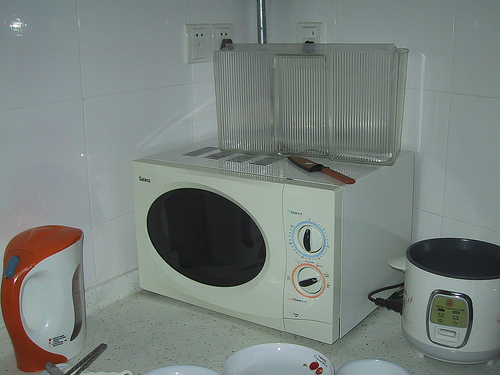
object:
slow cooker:
[402, 237, 499, 366]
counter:
[0, 291, 498, 373]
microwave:
[129, 134, 415, 345]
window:
[145, 184, 268, 287]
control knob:
[297, 224, 323, 252]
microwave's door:
[129, 157, 343, 345]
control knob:
[299, 267, 323, 293]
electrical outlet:
[183, 23, 212, 65]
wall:
[0, 0, 499, 328]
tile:
[77, 84, 195, 226]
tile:
[73, 0, 202, 101]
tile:
[0, 0, 96, 113]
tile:
[0, 96, 93, 247]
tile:
[328, 0, 461, 96]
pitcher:
[2, 225, 88, 372]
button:
[3, 255, 20, 278]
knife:
[287, 155, 356, 184]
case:
[211, 39, 408, 165]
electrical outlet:
[211, 22, 235, 50]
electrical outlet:
[297, 23, 324, 43]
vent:
[181, 146, 219, 156]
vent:
[205, 151, 233, 158]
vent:
[228, 154, 256, 163]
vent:
[249, 154, 287, 165]